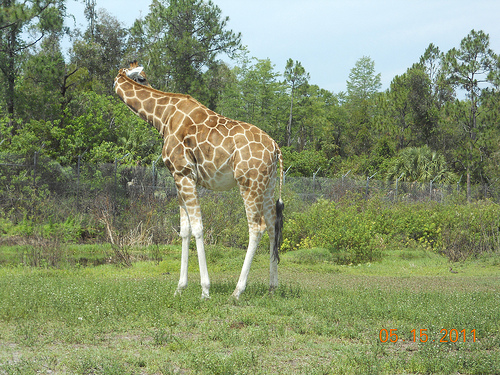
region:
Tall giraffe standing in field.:
[169, 242, 307, 324]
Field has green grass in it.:
[131, 267, 328, 348]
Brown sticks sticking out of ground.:
[63, 204, 164, 283]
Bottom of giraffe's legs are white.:
[165, 227, 278, 286]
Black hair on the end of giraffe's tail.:
[269, 201, 300, 281]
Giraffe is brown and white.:
[167, 87, 267, 219]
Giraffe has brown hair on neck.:
[137, 76, 196, 116]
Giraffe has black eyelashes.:
[138, 74, 152, 92]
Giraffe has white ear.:
[128, 65, 154, 85]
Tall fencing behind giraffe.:
[57, 152, 452, 213]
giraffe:
[109, 57, 306, 295]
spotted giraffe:
[104, 62, 295, 296]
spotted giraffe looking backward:
[95, 56, 292, 296]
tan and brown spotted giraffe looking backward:
[100, 54, 292, 305]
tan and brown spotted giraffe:
[102, 56, 296, 307]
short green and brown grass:
[31, 274, 150, 339]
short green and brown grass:
[152, 317, 289, 369]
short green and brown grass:
[302, 269, 339, 354]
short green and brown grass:
[349, 317, 451, 348]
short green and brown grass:
[344, 275, 454, 312]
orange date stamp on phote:
[359, 307, 489, 352]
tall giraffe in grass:
[82, 44, 327, 301]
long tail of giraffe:
[272, 142, 301, 269]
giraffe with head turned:
[97, 44, 210, 150]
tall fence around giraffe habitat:
[316, 167, 467, 214]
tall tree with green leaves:
[458, 36, 491, 233]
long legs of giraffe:
[165, 165, 237, 305]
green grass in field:
[37, 276, 224, 368]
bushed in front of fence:
[320, 198, 489, 258]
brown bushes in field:
[12, 227, 77, 271]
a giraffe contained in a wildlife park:
[112, 58, 284, 302]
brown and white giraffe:
[113, 60, 285, 300]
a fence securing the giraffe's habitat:
[1, 147, 498, 239]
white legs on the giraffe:
[177, 235, 274, 300]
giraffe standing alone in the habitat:
[7, 7, 492, 364]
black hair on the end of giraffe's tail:
[267, 195, 287, 265]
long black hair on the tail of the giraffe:
[272, 200, 283, 265]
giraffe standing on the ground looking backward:
[112, 59, 288, 301]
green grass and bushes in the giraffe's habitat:
[287, 194, 496, 373]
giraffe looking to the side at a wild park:
[1, 1, 498, 373]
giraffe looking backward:
[106, 68, 301, 303]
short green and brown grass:
[14, 272, 156, 351]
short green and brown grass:
[155, 309, 320, 354]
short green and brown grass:
[296, 273, 413, 368]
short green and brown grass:
[401, 265, 481, 354]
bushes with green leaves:
[308, 109, 444, 178]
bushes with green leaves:
[432, 204, 490, 244]